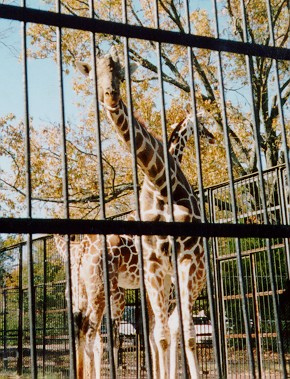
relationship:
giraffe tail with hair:
[69, 279, 95, 359] [70, 307, 87, 328]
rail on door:
[221, 289, 285, 301] [209, 183, 288, 366]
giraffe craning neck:
[47, 50, 216, 376] [79, 47, 179, 182]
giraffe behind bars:
[50, 34, 239, 331] [7, 4, 289, 377]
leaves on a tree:
[18, 18, 287, 216] [5, 2, 287, 212]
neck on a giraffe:
[94, 79, 189, 207] [81, 33, 227, 258]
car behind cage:
[191, 314, 214, 345] [0, 2, 287, 377]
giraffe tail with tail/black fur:
[71, 241, 85, 336] [66, 241, 90, 340]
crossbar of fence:
[5, 10, 289, 54] [5, 7, 288, 350]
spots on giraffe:
[118, 242, 131, 262] [47, 50, 216, 376]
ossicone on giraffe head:
[89, 52, 98, 67] [74, 45, 139, 112]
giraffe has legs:
[74, 45, 211, 379] [141, 272, 207, 377]